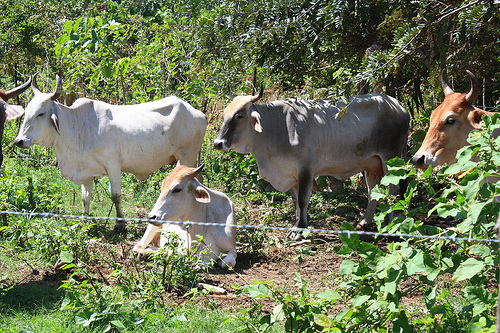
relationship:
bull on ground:
[14, 72, 208, 234] [3, 72, 499, 329]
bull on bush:
[412, 70, 499, 189] [337, 111, 495, 330]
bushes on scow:
[390, 151, 498, 326] [407, 78, 494, 165]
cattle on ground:
[6, 77, 489, 261] [3, 72, 499, 329]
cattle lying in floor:
[132, 159, 236, 268] [0, 119, 498, 330]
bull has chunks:
[14, 72, 208, 234] [52, 74, 69, 101]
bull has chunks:
[14, 72, 208, 234] [29, 72, 44, 91]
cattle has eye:
[132, 159, 236, 268] [165, 183, 187, 196]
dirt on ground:
[179, 191, 384, 311] [3, 72, 499, 329]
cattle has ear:
[132, 159, 236, 268] [196, 182, 210, 207]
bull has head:
[399, 65, 497, 192] [405, 63, 483, 183]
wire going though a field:
[3, 207, 498, 251] [7, 3, 498, 330]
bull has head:
[14, 72, 208, 234] [13, 75, 70, 152]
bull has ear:
[6, 87, 216, 250] [466, 98, 498, 125]